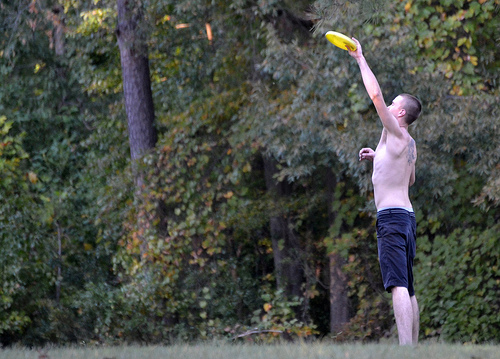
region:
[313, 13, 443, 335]
the man catching a frisbee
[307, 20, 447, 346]
the man with a frisbee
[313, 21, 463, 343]
the frisbee is yellow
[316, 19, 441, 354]
the man wearing shorts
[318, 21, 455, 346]
the shorts are blue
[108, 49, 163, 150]
the tree trunk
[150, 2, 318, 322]
the trees with leaves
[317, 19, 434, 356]
the man standing on the grass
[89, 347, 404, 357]
the grass is dry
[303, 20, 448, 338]
the man playing frisbee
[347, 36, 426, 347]
The man holding the frisbee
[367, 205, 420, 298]
The man's blue shorts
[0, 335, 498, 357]
The grass under the man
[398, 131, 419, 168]
The tattoo on the man's back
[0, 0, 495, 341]
The trees behind the man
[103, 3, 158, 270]
The tallest of the tree trunks shown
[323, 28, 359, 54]
The yellow frisbee shown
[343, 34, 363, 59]
The hand holding the frisbee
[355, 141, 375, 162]
The man's right hand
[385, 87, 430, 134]
The head of the man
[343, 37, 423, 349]
a shirtless man standing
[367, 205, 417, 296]
a pair of men's shorts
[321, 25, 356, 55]
a yellow frisbee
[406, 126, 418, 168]
a man's back tattoo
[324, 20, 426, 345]
a man catching a frisbee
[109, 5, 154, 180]
a large tree trunk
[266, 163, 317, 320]
a large tree trunk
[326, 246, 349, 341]
a large tree trunk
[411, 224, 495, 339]
a large green bush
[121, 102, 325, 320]
a large green tree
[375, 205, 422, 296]
the man's shorts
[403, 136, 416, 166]
the tattoo on the man's back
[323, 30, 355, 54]
the yellow frisbeen in the man's hand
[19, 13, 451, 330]
the trees behind the man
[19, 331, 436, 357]
the grass on the ground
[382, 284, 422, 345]
the man's calves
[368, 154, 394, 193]
the man's ribs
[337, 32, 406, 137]
the man's left arm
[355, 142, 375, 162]
the man's right hand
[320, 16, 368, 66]
yello frisbee in the air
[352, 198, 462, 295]
man's dark shorts on lower part of body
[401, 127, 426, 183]
tatoo on back of man's right shoulder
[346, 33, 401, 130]
man extending his left arm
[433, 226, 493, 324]
green leaves on the right side of photo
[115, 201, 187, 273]
golden leaves on tree trunk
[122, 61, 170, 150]
brown tree trunk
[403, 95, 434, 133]
man with dark shaved head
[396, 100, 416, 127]
left ear on man on the right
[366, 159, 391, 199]
bumps where ribs are located